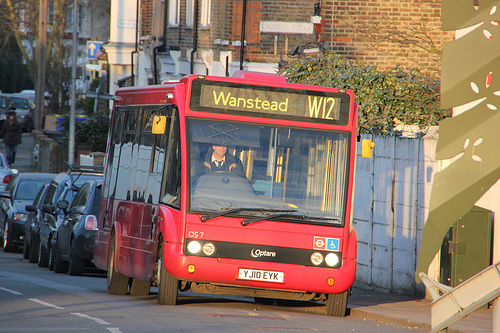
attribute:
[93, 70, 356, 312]
bus — red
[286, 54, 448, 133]
plants — growing, green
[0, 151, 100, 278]
cars — parked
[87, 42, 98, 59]
arrow — white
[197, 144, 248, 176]
man — sitting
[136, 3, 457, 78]
building — brown, brick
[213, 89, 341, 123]
letter — yellow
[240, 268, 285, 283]
plate — white